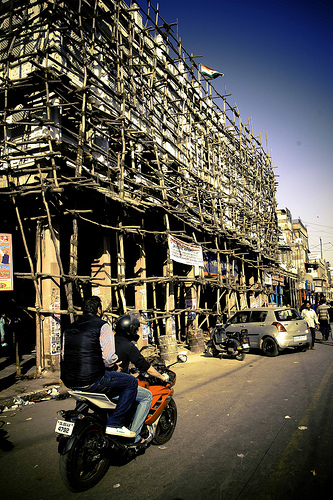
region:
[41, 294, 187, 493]
two people on a motorcycle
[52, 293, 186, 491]
two people on a red motorcycle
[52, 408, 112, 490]
the black rear fender of a motorcycle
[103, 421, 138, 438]
a white sneaker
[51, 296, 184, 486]
two riders but only one helmet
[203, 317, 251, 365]
a parked motorcycle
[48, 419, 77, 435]
white license plate with black lettering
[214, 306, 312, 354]
a small gray crossover vehicle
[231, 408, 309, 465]
debris in the street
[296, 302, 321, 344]
man facing the motorcycle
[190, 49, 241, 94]
a large Mexican flag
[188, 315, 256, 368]
a dusty black scooter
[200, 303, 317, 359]
a small silver suv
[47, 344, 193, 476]
a red and black bike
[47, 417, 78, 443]
a small white license plate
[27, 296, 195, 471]
two guys on a motorcycle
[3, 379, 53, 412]
a trash littered cub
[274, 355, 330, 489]
a faded yellow line on the road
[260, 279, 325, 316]
a few colorful poles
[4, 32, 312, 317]
a structure in process of being built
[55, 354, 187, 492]
a red street bike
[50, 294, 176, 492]
two people riding a motorcycle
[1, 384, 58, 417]
trash in the gutter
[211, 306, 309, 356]
a sports utility vehicle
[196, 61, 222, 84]
a flag waving in the wind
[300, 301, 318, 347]
a person wearing a white shirt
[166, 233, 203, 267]
a banner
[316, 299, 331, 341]
a person wearing a striped shirt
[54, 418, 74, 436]
a small license plate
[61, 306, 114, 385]
man wearing black vest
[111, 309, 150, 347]
man wearing black helmet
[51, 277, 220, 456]
men riding red motorcycle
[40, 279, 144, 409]
man is sitting behind other man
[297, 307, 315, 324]
man wearing white shirt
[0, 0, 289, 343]
structure made of sticks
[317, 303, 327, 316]
man's shirt is striped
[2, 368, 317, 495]
the road is dirty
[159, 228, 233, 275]
white sign hanging on structure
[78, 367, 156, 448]
men wearing blue jeans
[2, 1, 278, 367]
scaffolding around large building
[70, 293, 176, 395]
only the driver of the motorcycle is wearing a helmet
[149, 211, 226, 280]
banner hung from scaffolding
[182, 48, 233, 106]
flag hung from building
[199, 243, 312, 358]
tan vehicle in front of building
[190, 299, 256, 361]
parked motorbike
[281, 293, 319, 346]
man standing behind vehicle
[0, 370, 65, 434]
rubbish by the side of the road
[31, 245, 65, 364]
signs affixed to pillar